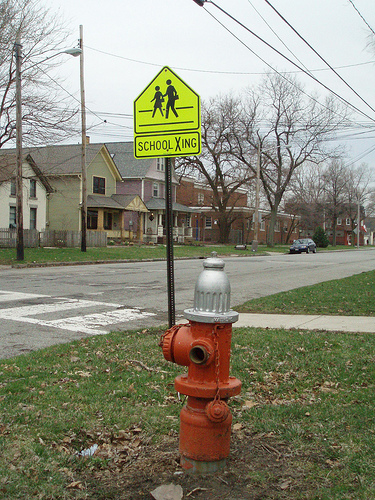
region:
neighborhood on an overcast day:
[2, 4, 373, 494]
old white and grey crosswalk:
[1, 282, 166, 355]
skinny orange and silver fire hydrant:
[157, 250, 257, 464]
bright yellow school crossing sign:
[127, 61, 207, 348]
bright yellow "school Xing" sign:
[122, 61, 203, 329]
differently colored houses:
[8, 129, 360, 262]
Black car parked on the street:
[286, 228, 325, 261]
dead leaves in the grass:
[243, 340, 367, 439]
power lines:
[202, 1, 372, 128]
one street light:
[2, 34, 86, 281]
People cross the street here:
[117, 63, 225, 171]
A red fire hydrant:
[135, 246, 281, 467]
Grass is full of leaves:
[18, 349, 161, 488]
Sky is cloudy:
[42, 1, 348, 154]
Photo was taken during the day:
[20, 9, 353, 221]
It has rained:
[18, 270, 288, 378]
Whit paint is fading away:
[13, 270, 160, 347]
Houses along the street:
[4, 141, 191, 270]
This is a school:
[171, 153, 302, 246]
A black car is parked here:
[281, 235, 335, 261]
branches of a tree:
[227, 96, 251, 137]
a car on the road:
[290, 235, 321, 254]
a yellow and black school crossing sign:
[130, 132, 207, 155]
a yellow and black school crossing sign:
[133, 65, 210, 130]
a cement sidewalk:
[268, 302, 342, 337]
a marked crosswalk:
[28, 288, 102, 334]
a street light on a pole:
[14, 41, 85, 83]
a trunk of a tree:
[214, 197, 231, 244]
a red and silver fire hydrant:
[157, 251, 264, 460]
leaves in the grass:
[252, 360, 291, 410]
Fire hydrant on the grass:
[158, 249, 242, 476]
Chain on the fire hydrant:
[211, 321, 223, 402]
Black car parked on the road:
[289, 236, 317, 253]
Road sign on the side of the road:
[133, 64, 198, 158]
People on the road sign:
[150, 78, 178, 118]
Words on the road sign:
[136, 135, 198, 151]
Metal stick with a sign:
[164, 154, 175, 328]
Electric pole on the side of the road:
[14, 28, 22, 262]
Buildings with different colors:
[2, 139, 373, 246]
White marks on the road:
[1, 288, 155, 335]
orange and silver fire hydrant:
[143, 232, 259, 471]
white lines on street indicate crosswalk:
[0, 282, 166, 348]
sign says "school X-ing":
[116, 58, 218, 178]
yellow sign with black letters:
[125, 55, 208, 180]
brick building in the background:
[175, 161, 326, 260]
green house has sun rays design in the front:
[64, 143, 155, 250]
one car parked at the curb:
[278, 228, 320, 263]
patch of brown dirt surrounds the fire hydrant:
[90, 397, 311, 494]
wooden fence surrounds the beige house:
[0, 137, 117, 254]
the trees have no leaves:
[0, 1, 373, 267]